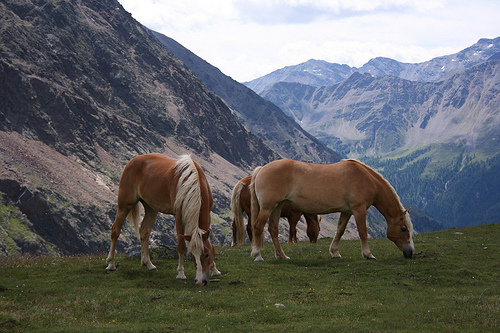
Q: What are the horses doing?
A: Eating.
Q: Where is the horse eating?
A: Grass.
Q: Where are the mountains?
A: Back of grass.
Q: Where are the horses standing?
A: Near mountains.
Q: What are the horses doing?
A: Eating grass.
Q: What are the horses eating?
A: Grass.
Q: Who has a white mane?
A: The horse.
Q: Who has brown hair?
A: The horse.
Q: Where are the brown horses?
A: On the grass.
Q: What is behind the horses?
A: Mountains.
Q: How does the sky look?
A: Cloudy.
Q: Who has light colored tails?
A: The horses.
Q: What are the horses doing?
A: Grazing.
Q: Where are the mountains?
A: Behind the horses.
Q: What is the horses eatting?
A: Grass.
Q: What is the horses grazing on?
A: Grass.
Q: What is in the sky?
A: Large white clouds.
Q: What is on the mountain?
A: Patch of green grass.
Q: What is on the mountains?
A: Dirt and rock.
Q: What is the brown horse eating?
A: Grass.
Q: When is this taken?
A: Daytime.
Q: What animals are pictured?
A: Horses.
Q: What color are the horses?
A: Tan.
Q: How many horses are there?
A: Three.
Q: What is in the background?
A: Mountains.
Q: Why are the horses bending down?
A: They are eating.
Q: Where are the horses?
A: A mountainside.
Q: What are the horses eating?
A: Grass.